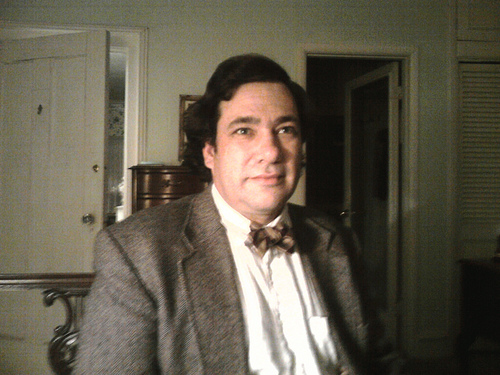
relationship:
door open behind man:
[0, 22, 120, 374] [67, 39, 407, 374]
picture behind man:
[166, 89, 253, 176] [57, 41, 444, 368]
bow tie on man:
[243, 220, 298, 259] [67, 39, 407, 374]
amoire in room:
[124, 158, 206, 219] [2, 0, 496, 372]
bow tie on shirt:
[243, 220, 298, 259] [93, 177, 388, 373]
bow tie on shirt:
[240, 220, 301, 257] [218, 205, 350, 374]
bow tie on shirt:
[243, 220, 298, 259] [203, 178, 345, 372]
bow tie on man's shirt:
[243, 220, 298, 259] [205, 182, 347, 374]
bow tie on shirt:
[243, 220, 298, 259] [230, 203, 335, 372]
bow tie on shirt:
[243, 220, 298, 259] [206, 191, 338, 373]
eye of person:
[235, 124, 255, 141] [195, 69, 337, 271]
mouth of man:
[247, 170, 288, 183] [67, 54, 407, 375]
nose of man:
[253, 123, 283, 165] [67, 39, 407, 374]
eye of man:
[271, 120, 298, 147] [178, 50, 337, 245]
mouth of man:
[246, 172, 285, 187] [67, 39, 407, 374]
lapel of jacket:
[293, 217, 351, 350] [60, 185, 392, 373]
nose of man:
[253, 123, 283, 165] [67, 54, 407, 375]